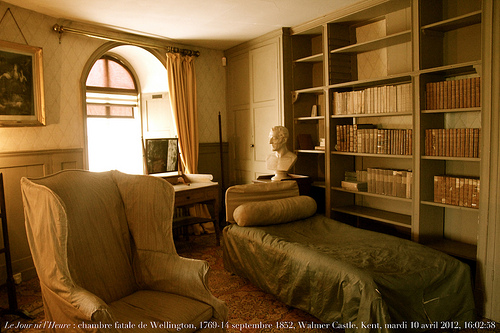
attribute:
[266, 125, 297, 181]
bust — statue, man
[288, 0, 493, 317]
bookshelf — large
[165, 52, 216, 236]
curtain — orange, drawn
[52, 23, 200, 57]
curtain rod — metal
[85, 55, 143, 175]
window — arched, large, open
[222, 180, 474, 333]
sofa chair — covered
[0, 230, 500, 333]
floor — carpeted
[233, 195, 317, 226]
pillow — white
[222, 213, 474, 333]
cover — green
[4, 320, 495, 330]
text — white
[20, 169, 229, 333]
chair — empty